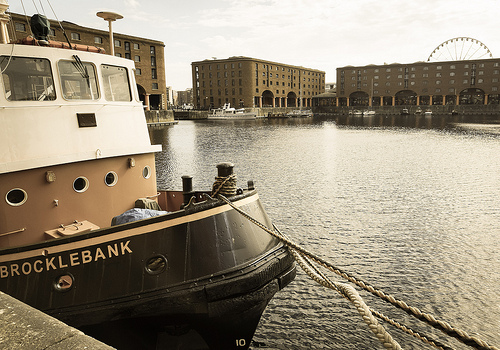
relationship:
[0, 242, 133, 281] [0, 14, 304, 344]
name on boat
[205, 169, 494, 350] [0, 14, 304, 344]
rope on boat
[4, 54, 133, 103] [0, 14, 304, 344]
windows on boat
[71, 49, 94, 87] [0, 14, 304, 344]
wiper on boat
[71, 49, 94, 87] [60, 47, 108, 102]
wiper on windshield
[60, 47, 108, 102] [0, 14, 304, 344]
windshield on boat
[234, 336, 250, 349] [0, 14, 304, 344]
number 10 on boat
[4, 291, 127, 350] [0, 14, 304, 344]
dock by boat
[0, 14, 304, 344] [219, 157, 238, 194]
boat has post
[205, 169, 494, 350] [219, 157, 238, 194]
rope on post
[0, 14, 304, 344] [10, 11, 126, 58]
boat has rigging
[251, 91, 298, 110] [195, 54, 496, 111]
walking path under buildings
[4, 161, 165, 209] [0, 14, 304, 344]
windows on boat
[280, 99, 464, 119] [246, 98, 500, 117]
boats along wall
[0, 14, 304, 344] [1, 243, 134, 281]
boat has name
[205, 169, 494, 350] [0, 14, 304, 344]
rope holding boat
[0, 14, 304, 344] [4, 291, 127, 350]
boat tied to dock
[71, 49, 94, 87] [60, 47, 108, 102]
wiper for windshield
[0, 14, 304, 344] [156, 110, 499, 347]
boat in water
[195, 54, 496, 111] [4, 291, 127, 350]
buildings beside dock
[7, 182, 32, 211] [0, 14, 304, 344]
porthole on boat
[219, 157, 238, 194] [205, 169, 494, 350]
post for rope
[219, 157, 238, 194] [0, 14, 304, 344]
post holds boat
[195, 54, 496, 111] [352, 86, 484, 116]
buildings have arches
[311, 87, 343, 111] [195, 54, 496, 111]
awning between buildings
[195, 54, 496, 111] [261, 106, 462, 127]
buildings have shadow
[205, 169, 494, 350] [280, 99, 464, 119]
rope holding boats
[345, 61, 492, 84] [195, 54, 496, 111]
windows on buildings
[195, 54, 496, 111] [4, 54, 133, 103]
buildings have windows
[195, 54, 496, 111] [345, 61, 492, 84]
buildings have windows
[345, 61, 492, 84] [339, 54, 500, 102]
windows on building